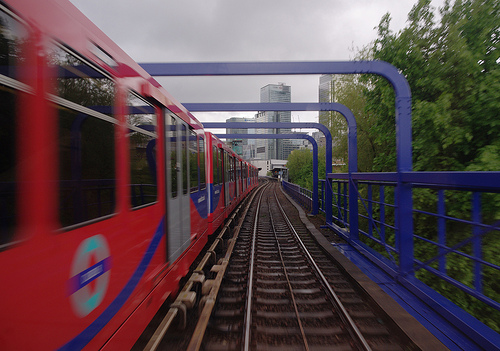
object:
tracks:
[20, 9, 486, 349]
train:
[1, 2, 262, 345]